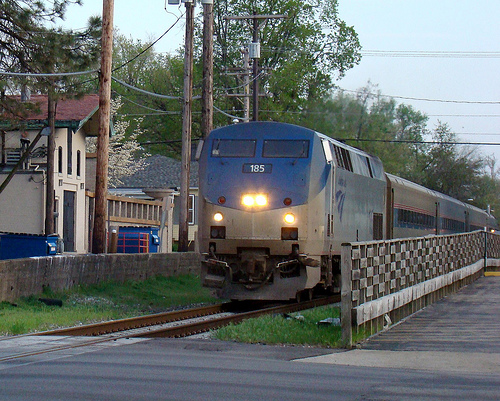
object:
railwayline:
[0, 311, 346, 376]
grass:
[0, 270, 385, 350]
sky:
[10, 0, 500, 176]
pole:
[91, 0, 117, 256]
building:
[0, 92, 118, 262]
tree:
[174, 0, 364, 123]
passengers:
[399, 211, 402, 221]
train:
[194, 118, 499, 306]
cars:
[385, 172, 439, 240]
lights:
[283, 198, 293, 206]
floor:
[0, 271, 500, 400]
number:
[249, 164, 264, 172]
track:
[120, 295, 339, 338]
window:
[263, 139, 310, 158]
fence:
[340, 226, 499, 350]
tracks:
[212, 306, 279, 321]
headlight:
[240, 192, 268, 207]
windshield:
[210, 139, 310, 158]